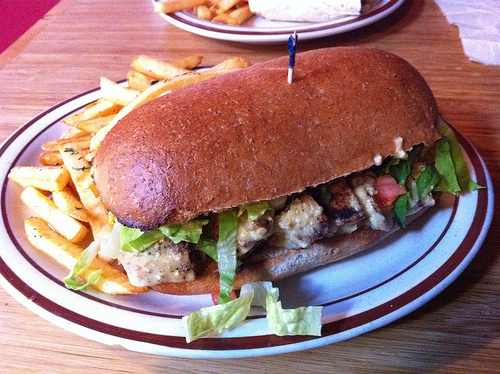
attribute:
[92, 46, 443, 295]
bun — brown, here, burnt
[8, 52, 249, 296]
fries — here, golden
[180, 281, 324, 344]
lettuce — partial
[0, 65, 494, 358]
plate — colored, white, here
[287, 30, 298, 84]
toothpick — here, white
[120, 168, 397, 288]
meat — here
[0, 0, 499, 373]
table — wooden, partial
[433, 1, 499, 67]
napkin — white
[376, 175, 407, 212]
tomato — here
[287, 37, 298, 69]
end — blue